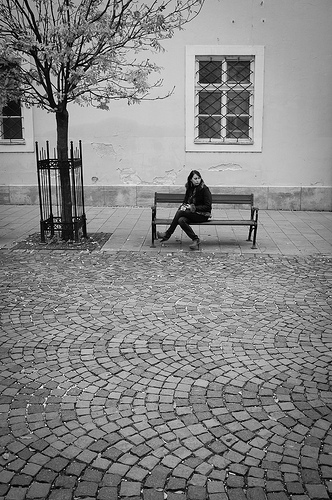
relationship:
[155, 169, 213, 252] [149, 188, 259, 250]
lady on bench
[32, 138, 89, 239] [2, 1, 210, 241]
gate around tree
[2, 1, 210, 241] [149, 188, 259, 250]
tree next to bench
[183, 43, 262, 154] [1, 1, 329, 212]
window on wall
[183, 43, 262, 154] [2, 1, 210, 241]
window behind tree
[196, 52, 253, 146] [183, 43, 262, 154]
wire over window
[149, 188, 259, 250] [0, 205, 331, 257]
bench on sidewalk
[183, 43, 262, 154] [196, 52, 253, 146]
window with wire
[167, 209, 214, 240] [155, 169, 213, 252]
jeans on lady